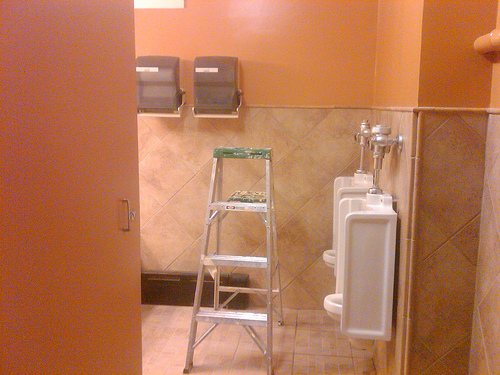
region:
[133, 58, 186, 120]
The paper towel dispenser on the left.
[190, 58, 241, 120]
The paper towel dispenser on the right.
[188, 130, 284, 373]
The ladder in front of the urinals.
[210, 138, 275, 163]
The green top of the ladder.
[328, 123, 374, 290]
The urinal on the left.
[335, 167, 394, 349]
The urinal on the right.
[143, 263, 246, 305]
The black object against the wall under the paper towel dispensers.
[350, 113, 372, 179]
The metal flusher above the urinal on the left.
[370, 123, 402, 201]
The metal flusher above the urinal on the right.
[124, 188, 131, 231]
The handle to the open bathroom stall door.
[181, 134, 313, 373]
The ladder is set up in the bathroom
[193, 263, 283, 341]
First rung of the ladder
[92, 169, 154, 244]
Silver handle on the door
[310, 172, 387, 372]
Urinals hanging on the wall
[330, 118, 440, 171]
Flush handle for the urinal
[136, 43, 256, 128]
Paper towel holders on the wall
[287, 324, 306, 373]
Crack in between the tile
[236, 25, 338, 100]
The wall is smooth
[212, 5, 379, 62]
Light shining on the wall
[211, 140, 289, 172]
Top rung of the ladder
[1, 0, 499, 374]
Latter in the middle of the men's bathroom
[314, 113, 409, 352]
Men's urinal hanging on the wall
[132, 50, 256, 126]
Paper towel dispensers hanging on the wall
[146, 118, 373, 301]
Ceramic tile on the wall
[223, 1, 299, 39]
Light reflecting on the wall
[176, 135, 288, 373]
Tall aluminum latter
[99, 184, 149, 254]
Handle and lock on bathroom door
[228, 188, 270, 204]
Dried paint on the latter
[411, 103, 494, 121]
Rounded tile border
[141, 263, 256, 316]
Black box along the wall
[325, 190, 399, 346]
a white porcelain urinal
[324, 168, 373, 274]
a white porcelain urinal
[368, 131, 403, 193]
a chrome flush valve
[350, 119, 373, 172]
a chrome flush valve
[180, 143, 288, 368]
a short aluminum ladder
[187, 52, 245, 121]
a paper towel dispenser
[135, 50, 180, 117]
a paper towel dispenser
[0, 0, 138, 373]
an orange open door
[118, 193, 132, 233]
a door pull handle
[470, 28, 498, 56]
an orange painted pipe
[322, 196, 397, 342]
urinal in the foreground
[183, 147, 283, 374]
metal step ladder to the left of urinals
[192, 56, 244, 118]
paper towel dispenser nearest the step ladder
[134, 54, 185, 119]
paper towel dispenser to the left of the first dispenser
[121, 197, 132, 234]
a handle on an orange door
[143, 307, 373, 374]
bathroom tile floor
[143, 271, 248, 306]
dark brown rectangle shaped object against wall on left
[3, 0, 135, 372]
door with handle on the left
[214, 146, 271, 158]
green top of the step ladder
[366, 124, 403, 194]
silver plumbing connection on top of first urinal